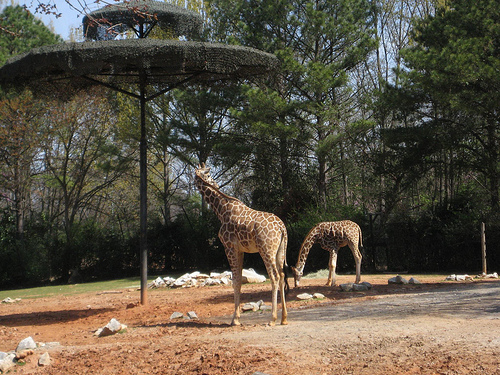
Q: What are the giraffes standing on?
A: Flat ground.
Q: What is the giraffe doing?
A: Looking at the ground.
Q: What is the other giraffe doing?
A: Looking at the other one.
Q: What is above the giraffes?
A: What looks like a tall sculpture.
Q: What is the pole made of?
A: Metal.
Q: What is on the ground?
A: Stones.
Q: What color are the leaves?
A: Green.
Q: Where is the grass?
A: By the trees.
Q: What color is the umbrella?
A: Black.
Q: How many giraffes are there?
A: Two.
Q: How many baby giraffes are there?
A: One.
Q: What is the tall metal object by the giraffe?
A: Metal canopy.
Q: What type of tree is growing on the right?
A: Evergreen.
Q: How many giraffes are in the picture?
A: Two.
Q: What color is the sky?
A: Blue.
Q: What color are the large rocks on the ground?
A: White.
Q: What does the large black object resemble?
A: Umbrella.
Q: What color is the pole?
A: Black.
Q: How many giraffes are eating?
A: One.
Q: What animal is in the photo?
A: Giraffe.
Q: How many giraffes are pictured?
A: Two.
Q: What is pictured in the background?
A: Trees.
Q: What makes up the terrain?
A: Dirt.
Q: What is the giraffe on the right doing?
A: Eating.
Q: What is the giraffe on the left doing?
A: Standing.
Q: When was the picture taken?
A: Daytime.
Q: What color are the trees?
A: Green.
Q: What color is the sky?
A: Blue.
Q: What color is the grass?
A: Green.